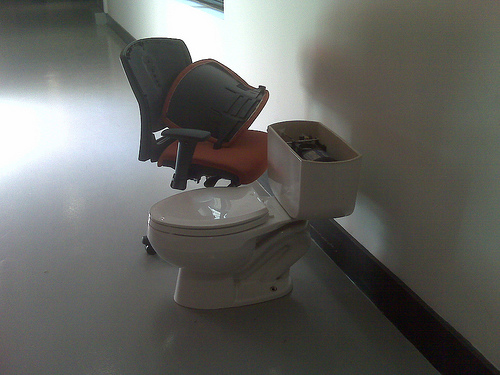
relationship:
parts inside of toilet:
[288, 113, 335, 174] [133, 81, 423, 296]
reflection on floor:
[3, 81, 110, 176] [3, 5, 448, 370]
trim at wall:
[103, 12, 499, 372] [364, 2, 498, 373]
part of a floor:
[92, 344, 152, 375] [3, 5, 448, 370]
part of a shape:
[167, 343, 298, 375] [393, 156, 471, 304]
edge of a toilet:
[163, 217, 251, 235] [134, 116, 364, 315]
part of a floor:
[117, 286, 255, 375] [3, 5, 448, 370]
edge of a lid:
[163, 220, 251, 283] [145, 178, 276, 238]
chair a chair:
[119, 37, 267, 190] [119, 32, 279, 196]